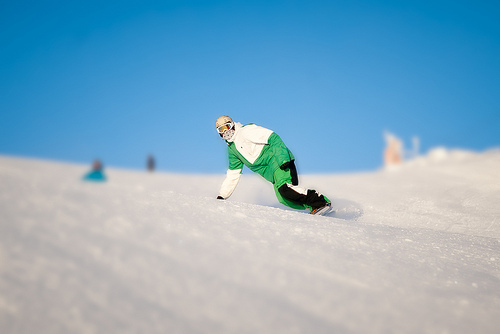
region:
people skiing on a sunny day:
[6, 8, 494, 323]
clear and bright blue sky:
[34, 20, 349, 113]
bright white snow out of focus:
[47, 193, 235, 300]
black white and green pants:
[274, 168, 316, 215]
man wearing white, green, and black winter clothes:
[212, 110, 313, 220]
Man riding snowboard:
[204, 111, 341, 217]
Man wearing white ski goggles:
[212, 113, 237, 140]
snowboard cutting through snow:
[305, 197, 335, 219]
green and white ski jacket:
[213, 130, 290, 185]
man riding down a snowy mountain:
[201, 101, 357, 245]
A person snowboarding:
[211, 102, 341, 237]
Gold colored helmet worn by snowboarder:
[168, 112, 248, 154]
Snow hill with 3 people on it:
[23, 87, 285, 322]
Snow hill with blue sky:
[336, 25, 498, 332]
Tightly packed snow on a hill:
[33, 215, 482, 321]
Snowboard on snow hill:
[285, 195, 368, 231]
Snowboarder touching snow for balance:
[200, 121, 265, 247]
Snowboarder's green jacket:
[198, 134, 312, 172]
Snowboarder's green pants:
[262, 155, 353, 234]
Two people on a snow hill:
[45, 125, 175, 280]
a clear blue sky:
[25, 16, 132, 86]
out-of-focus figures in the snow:
[75, 140, 165, 190]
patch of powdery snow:
[360, 225, 490, 310]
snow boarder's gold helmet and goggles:
[210, 110, 235, 140]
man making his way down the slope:
[185, 90, 345, 220]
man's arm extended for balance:
[205, 165, 240, 200]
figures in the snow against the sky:
[365, 100, 465, 175]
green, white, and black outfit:
[225, 135, 305, 191]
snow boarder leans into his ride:
[177, 76, 407, 256]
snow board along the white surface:
[303, 198, 366, 221]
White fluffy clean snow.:
[16, 146, 479, 323]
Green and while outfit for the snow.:
[206, 107, 341, 226]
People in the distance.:
[81, 145, 166, 197]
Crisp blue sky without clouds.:
[9, 8, 492, 181]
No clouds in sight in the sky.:
[10, 21, 489, 203]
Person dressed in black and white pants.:
[272, 155, 340, 220]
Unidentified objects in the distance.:
[361, 121, 453, 175]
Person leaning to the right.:
[204, 112, 348, 232]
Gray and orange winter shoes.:
[298, 197, 338, 221]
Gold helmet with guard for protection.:
[208, 108, 339, 220]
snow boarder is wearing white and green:
[213, 114, 367, 219]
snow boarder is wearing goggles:
[212, 113, 235, 142]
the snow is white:
[0, 147, 499, 332]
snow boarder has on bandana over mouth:
[222, 128, 234, 143]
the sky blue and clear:
[1, 0, 498, 175]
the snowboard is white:
[307, 197, 334, 219]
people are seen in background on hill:
[83, 149, 160, 186]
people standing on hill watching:
[382, 125, 423, 172]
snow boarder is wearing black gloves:
[213, 159, 290, 201]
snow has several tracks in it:
[0, 176, 495, 329]